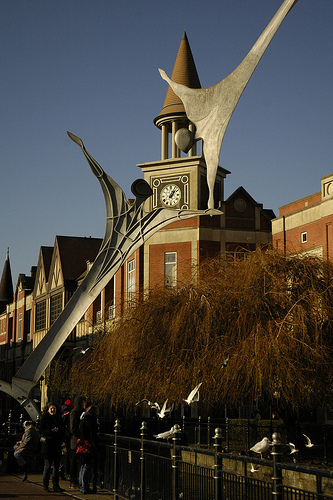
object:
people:
[0, 397, 97, 495]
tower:
[152, 29, 203, 161]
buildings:
[0, 31, 333, 414]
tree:
[44, 242, 333, 457]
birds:
[135, 382, 203, 442]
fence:
[99, 419, 332, 499]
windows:
[92, 251, 178, 326]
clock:
[160, 183, 182, 207]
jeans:
[77, 464, 91, 489]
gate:
[79, 419, 122, 500]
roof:
[278, 189, 322, 210]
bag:
[76, 438, 93, 454]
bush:
[45, 242, 333, 446]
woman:
[75, 406, 101, 495]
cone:
[153, 31, 202, 135]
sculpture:
[0, 0, 294, 428]